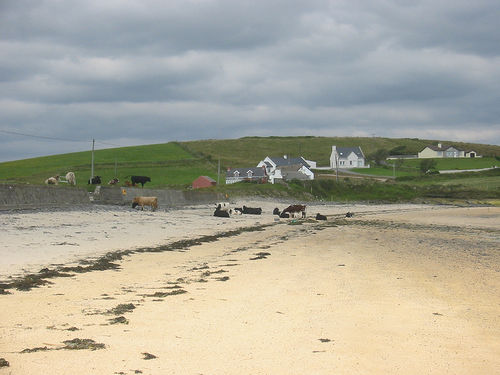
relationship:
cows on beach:
[126, 190, 332, 228] [9, 223, 471, 372]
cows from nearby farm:
[126, 190, 332, 228] [220, 138, 482, 185]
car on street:
[425, 168, 440, 175] [437, 165, 500, 174]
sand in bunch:
[2, 206, 498, 370] [1, 196, 491, 371]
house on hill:
[417, 141, 447, 159] [177, 121, 307, 181]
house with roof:
[417, 139, 477, 159] [416, 141, 465, 151]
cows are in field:
[198, 160, 337, 252] [257, 187, 456, 344]